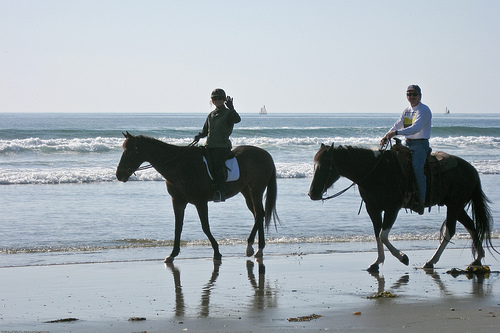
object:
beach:
[2, 234, 499, 331]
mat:
[203, 157, 240, 183]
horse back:
[171, 144, 258, 165]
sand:
[0, 242, 499, 332]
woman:
[192, 88, 241, 203]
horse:
[116, 130, 284, 263]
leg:
[192, 200, 221, 261]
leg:
[164, 195, 189, 263]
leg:
[247, 181, 267, 257]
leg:
[242, 187, 265, 258]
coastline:
[0, 234, 499, 272]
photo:
[1, 0, 499, 331]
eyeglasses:
[211, 96, 226, 100]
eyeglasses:
[406, 92, 422, 96]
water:
[0, 112, 499, 258]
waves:
[1, 137, 498, 152]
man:
[380, 85, 431, 215]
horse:
[308, 142, 500, 274]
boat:
[258, 104, 268, 115]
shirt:
[386, 102, 433, 140]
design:
[403, 112, 416, 129]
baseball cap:
[407, 84, 420, 93]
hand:
[225, 96, 234, 107]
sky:
[0, 1, 499, 113]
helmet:
[211, 88, 226, 98]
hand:
[194, 135, 201, 141]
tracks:
[288, 314, 326, 324]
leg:
[379, 203, 410, 267]